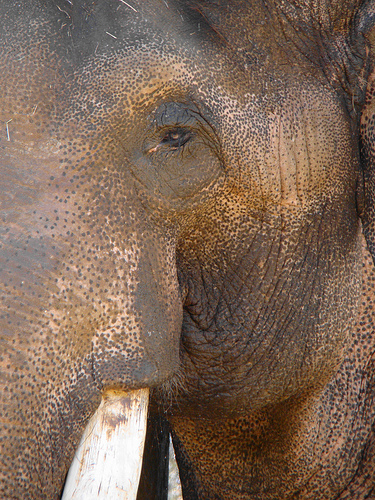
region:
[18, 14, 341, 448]
the face of an elephant.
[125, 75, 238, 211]
the eye of an elephant.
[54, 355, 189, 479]
the tusk of an elephant.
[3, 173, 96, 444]
part of an elephant trunk.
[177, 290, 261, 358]
some wrinkles on an elephant.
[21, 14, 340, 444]
a face view of a mighty elephant.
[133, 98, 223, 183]
one eye of a mighty elephant.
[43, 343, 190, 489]
part of a tusk of a mighty elephant.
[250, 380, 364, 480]
skin area of an elephant.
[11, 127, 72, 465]
part of the trunk of a mighty elephant.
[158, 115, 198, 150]
the eye of an elephant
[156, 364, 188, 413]
hair on an elephant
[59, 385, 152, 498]
the white tusk of an elephant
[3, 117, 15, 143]
a piece of straw on an elephant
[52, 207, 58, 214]
a black spot on the elephant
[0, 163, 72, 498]
the trunk of an elephant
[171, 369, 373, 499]
the leg of an elephant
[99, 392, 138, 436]
brown spots on an elephant's tusk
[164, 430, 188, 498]
the ground behind an elephant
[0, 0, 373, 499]
a brown elephant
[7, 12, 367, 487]
An extreme close up.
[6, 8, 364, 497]
Wildlife portrait.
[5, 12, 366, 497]
Aged, male elephant, seen close up.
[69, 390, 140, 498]
White tusk, showing damage.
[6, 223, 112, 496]
Discoloration on trunk.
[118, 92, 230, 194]
Small, very deep-set dark eye of elephant.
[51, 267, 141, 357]
Dots, indicating how close the shot is.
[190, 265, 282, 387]
Aged, sagging flesh of elephant.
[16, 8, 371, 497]
Left half of a facial shot of an elderly, male elephant.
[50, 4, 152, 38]
White hairs on elephant's head.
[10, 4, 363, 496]
An elephant is in the photo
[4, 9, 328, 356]
Only one eye is visible on the elephant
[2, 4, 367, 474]
You can't see the elephants ears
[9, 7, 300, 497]
The elephant has a tusk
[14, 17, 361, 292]
The elephant's eye is small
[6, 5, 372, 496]
There is only one elephant in the photo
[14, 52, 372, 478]
The elephant is brown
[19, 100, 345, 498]
The elephant's tusk is white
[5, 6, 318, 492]
You can see some of the elephant's trunk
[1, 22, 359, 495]
The elephant's tusk is ivory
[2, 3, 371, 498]
Left front view of an elephant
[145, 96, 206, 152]
Left eye of the elephant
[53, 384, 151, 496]
Top portion of the left tusk of the elephant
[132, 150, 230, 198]
Eye bags beneath the eye of the elephant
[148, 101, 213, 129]
Left eye lid of the elephant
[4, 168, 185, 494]
Left side of the elephant's horn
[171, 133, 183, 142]
Left pupil of the elephant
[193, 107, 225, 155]
Wrinkles on the elephant's left eye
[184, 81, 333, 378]
Wrinkles on the left side of the elephant's head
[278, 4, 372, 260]
Section of the elephant's left ear